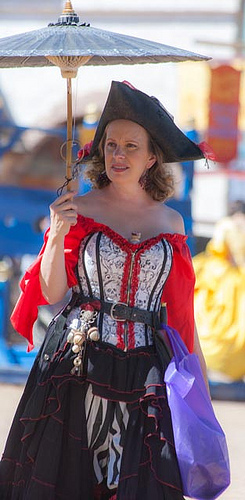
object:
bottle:
[129, 231, 141, 244]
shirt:
[9, 212, 195, 363]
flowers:
[78, 140, 93, 158]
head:
[102, 120, 160, 189]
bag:
[160, 322, 231, 498]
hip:
[37, 316, 166, 373]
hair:
[146, 141, 178, 200]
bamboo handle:
[43, 53, 94, 206]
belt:
[70, 292, 167, 328]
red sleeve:
[167, 234, 194, 354]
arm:
[188, 316, 208, 390]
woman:
[0, 77, 210, 499]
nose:
[113, 141, 125, 161]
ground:
[0, 373, 245, 497]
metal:
[110, 301, 128, 321]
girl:
[1, 80, 211, 498]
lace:
[5, 374, 186, 493]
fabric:
[11, 273, 43, 353]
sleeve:
[63, 227, 79, 287]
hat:
[73, 79, 216, 168]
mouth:
[111, 161, 130, 173]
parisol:
[0, 1, 213, 226]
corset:
[12, 214, 196, 353]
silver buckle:
[110, 299, 128, 321]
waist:
[70, 283, 167, 334]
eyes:
[106, 141, 116, 147]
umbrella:
[0, 1, 214, 251]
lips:
[112, 163, 130, 167]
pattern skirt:
[79, 384, 132, 492]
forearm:
[38, 234, 68, 307]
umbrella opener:
[46, 57, 92, 80]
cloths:
[93, 235, 166, 346]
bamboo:
[60, 0, 76, 15]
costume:
[0, 212, 196, 498]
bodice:
[70, 230, 174, 350]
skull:
[104, 281, 116, 301]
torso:
[52, 237, 175, 354]